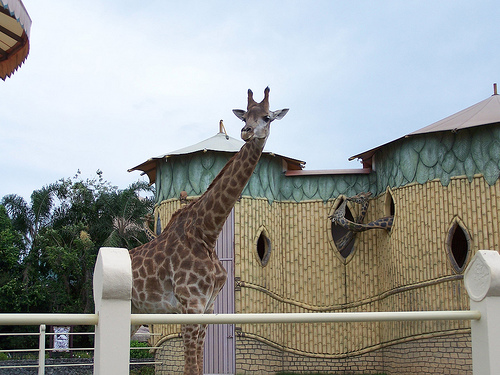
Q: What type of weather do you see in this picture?
A: It is clear.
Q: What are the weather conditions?
A: It is clear.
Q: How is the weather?
A: It is clear.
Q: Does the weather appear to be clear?
A: Yes, it is clear.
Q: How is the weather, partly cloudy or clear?
A: It is clear.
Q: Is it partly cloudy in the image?
A: No, it is clear.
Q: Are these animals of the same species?
A: Yes, all the animals are giraffes.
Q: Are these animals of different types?
A: No, all the animals are giraffes.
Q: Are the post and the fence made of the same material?
A: No, the post is made of wood and the fence is made of metal.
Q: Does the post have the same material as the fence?
A: No, the post is made of wood and the fence is made of metal.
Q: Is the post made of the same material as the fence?
A: No, the post is made of wood and the fence is made of metal.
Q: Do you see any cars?
A: No, there are no cars.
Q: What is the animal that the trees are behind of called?
A: The animal is a giraffe.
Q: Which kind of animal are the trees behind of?
A: The trees are behind the giraffe.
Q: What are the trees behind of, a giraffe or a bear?
A: The trees are behind a giraffe.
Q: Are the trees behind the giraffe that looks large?
A: Yes, the trees are behind the giraffe.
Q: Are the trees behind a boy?
A: No, the trees are behind the giraffe.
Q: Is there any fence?
A: Yes, there is a fence.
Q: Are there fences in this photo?
A: Yes, there is a fence.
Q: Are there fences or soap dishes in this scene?
A: Yes, there is a fence.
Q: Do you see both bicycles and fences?
A: No, there is a fence but no bicycles.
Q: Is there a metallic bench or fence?
A: Yes, there is a metal fence.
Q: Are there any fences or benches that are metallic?
A: Yes, the fence is metallic.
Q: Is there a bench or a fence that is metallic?
A: Yes, the fence is metallic.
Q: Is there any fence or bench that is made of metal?
A: Yes, the fence is made of metal.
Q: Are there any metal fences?
A: Yes, there is a metal fence.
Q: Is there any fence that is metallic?
A: Yes, there is a fence that is metallic.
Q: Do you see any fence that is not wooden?
A: Yes, there is a metallic fence.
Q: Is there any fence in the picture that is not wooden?
A: Yes, there is a metallic fence.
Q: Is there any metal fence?
A: Yes, there is a fence that is made of metal.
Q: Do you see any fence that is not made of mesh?
A: Yes, there is a fence that is made of metal.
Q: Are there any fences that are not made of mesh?
A: Yes, there is a fence that is made of metal.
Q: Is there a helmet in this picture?
A: No, there are no helmets.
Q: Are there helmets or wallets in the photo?
A: No, there are no helmets or wallets.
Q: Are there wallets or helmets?
A: No, there are no helmets or wallets.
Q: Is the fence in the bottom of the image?
A: Yes, the fence is in the bottom of the image.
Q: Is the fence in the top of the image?
A: No, the fence is in the bottom of the image.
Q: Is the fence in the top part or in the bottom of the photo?
A: The fence is in the bottom of the image.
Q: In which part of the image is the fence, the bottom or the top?
A: The fence is in the bottom of the image.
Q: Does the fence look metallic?
A: Yes, the fence is metallic.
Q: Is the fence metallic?
A: Yes, the fence is metallic.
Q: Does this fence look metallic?
A: Yes, the fence is metallic.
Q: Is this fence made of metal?
A: Yes, the fence is made of metal.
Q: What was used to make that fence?
A: The fence is made of metal.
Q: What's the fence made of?
A: The fence is made of metal.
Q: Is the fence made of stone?
A: No, the fence is made of metal.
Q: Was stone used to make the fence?
A: No, the fence is made of metal.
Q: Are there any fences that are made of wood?
A: No, there is a fence but it is made of metal.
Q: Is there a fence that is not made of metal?
A: No, there is a fence but it is made of metal.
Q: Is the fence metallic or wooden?
A: The fence is metallic.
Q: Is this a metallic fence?
A: Yes, this is a metallic fence.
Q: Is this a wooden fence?
A: No, this is a metallic fence.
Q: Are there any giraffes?
A: Yes, there is a giraffe.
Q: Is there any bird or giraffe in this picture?
A: Yes, there is a giraffe.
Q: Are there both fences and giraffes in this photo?
A: Yes, there are both a giraffe and a fence.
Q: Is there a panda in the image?
A: No, there are no pandas.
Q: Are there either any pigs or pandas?
A: No, there are no pandas or pigs.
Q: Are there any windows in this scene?
A: Yes, there is a window.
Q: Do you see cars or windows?
A: Yes, there is a window.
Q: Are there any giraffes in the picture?
A: Yes, there is a giraffe.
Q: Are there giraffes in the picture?
A: Yes, there is a giraffe.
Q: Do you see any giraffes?
A: Yes, there is a giraffe.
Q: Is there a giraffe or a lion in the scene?
A: Yes, there is a giraffe.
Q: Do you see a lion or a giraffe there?
A: Yes, there is a giraffe.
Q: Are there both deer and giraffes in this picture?
A: No, there is a giraffe but no deer.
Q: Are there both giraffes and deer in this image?
A: No, there is a giraffe but no deer.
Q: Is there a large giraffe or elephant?
A: Yes, there is a large giraffe.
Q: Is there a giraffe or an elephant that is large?
A: Yes, the giraffe is large.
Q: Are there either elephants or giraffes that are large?
A: Yes, the giraffe is large.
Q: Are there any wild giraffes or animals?
A: Yes, there is a wild giraffe.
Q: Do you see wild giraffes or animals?
A: Yes, there is a wild giraffe.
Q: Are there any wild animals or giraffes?
A: Yes, there is a wild giraffe.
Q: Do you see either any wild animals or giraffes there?
A: Yes, there is a wild giraffe.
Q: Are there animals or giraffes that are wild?
A: Yes, the giraffe is wild.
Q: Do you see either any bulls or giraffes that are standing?
A: Yes, the giraffe is standing.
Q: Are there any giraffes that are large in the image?
A: Yes, there is a large giraffe.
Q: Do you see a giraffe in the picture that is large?
A: Yes, there is a giraffe that is large.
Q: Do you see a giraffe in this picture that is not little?
A: Yes, there is a large giraffe.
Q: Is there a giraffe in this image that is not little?
A: Yes, there is a large giraffe.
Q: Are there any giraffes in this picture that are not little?
A: Yes, there is a large giraffe.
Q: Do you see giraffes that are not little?
A: Yes, there is a large giraffe.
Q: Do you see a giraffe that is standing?
A: Yes, there is a giraffe that is standing.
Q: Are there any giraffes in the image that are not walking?
A: Yes, there is a giraffe that is standing.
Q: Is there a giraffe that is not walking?
A: Yes, there is a giraffe that is standing.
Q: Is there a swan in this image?
A: No, there are no swans.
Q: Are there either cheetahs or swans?
A: No, there are no swans or cheetahs.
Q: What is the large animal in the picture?
A: The animal is a giraffe.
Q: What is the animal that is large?
A: The animal is a giraffe.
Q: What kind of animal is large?
A: The animal is a giraffe.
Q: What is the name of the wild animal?
A: The animal is a giraffe.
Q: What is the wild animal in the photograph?
A: The animal is a giraffe.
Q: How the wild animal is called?
A: The animal is a giraffe.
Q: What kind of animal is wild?
A: The animal is a giraffe.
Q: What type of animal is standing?
A: The animal is a giraffe.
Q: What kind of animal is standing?
A: The animal is a giraffe.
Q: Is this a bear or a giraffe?
A: This is a giraffe.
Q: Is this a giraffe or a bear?
A: This is a giraffe.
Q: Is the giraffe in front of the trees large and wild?
A: Yes, the giraffe is large and wild.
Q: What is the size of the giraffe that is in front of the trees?
A: The giraffe is large.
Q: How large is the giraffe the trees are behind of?
A: The giraffe is large.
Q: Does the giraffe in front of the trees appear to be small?
A: No, the giraffe is large.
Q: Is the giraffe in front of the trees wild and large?
A: Yes, the giraffe is wild and large.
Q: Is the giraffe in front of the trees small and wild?
A: No, the giraffe is wild but large.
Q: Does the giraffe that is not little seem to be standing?
A: Yes, the giraffe is standing.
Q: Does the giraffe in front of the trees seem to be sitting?
A: No, the giraffe is standing.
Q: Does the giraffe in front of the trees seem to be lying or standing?
A: The giraffe is standing.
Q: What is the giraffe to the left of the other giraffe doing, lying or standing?
A: The giraffe is standing.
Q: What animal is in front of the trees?
A: The giraffe is in front of the trees.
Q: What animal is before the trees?
A: The giraffe is in front of the trees.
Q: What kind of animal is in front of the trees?
A: The animal is a giraffe.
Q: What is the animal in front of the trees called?
A: The animal is a giraffe.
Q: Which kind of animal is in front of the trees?
A: The animal is a giraffe.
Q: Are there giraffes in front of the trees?
A: Yes, there is a giraffe in front of the trees.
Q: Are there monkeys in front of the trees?
A: No, there is a giraffe in front of the trees.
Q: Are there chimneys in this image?
A: No, there are no chimneys.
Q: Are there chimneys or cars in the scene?
A: No, there are no chimneys or cars.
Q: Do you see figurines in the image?
A: No, there are no figurines.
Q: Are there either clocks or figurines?
A: No, there are no figurines or clocks.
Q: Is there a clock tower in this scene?
A: No, there are no clock towers.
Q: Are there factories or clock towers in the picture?
A: No, there are no clock towers or factories.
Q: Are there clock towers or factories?
A: No, there are no clock towers or factories.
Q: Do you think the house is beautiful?
A: Yes, the house is beautiful.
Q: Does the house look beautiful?
A: Yes, the house is beautiful.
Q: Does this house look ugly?
A: No, the house is beautiful.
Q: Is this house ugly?
A: No, the house is beautiful.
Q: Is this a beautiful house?
A: Yes, this is a beautiful house.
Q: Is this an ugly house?
A: No, this is a beautiful house.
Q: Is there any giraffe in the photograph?
A: Yes, there are giraffes.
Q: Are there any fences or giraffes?
A: Yes, there are giraffes.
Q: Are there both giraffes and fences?
A: Yes, there are both giraffes and a fence.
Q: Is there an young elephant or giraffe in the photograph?
A: Yes, there are young giraffes.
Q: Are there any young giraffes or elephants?
A: Yes, there are young giraffes.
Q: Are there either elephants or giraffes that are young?
A: Yes, the giraffes are young.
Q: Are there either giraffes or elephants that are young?
A: Yes, the giraffes are young.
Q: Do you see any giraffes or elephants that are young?
A: Yes, the giraffes are young.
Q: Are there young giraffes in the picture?
A: Yes, there are young giraffes.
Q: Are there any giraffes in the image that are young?
A: Yes, there are giraffes that are young.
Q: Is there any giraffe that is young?
A: Yes, there are giraffes that are young.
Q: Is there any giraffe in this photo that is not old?
A: Yes, there are young giraffes.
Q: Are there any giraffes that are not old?
A: Yes, there are young giraffes.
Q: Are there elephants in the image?
A: No, there are no elephants.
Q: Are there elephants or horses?
A: No, there are no elephants or horses.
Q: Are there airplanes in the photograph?
A: No, there are no airplanes.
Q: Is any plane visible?
A: No, there are no airplanes.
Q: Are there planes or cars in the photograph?
A: No, there are no planes or cars.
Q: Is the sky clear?
A: Yes, the sky is clear.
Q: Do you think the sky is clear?
A: Yes, the sky is clear.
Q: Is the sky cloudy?
A: No, the sky is clear.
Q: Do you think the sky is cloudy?
A: No, the sky is clear.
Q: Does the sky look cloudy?
A: No, the sky is clear.